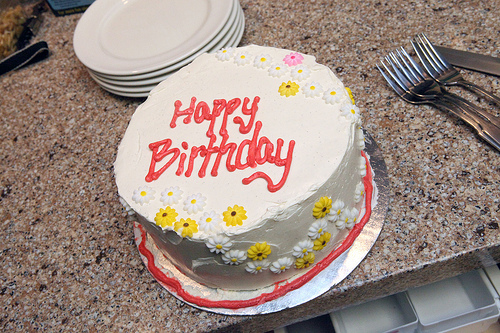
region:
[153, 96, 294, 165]
frosting that spells out Happy Birthday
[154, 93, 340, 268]
white frosted cake with flower decorations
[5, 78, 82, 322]
granite kitchen countertop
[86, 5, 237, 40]
stack of white plates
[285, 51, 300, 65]
pink flower on the cake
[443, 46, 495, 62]
knife on the countertop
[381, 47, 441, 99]
four forks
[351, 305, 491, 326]
white storage containers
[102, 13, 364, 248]
Birthday cake next to five plates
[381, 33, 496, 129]
knife and forks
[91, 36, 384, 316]
white birthday cake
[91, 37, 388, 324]
white birthday cake with red lettering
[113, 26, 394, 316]
white cake with daisy candy decorations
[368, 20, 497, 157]
four silver forks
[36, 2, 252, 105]
five white plates on a counter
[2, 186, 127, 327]
beige granite countertop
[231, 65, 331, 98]
yellow and white candy decorations atop a cake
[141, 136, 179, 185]
red icing B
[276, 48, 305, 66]
pink candy daisy decoration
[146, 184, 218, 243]
two yellow and two white daisy decorations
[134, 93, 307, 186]
letters in red frosting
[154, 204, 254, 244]
white and yellow frosting flowers on cake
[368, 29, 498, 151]
forks on countertop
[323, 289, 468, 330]
open drawer beneath counter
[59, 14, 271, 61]
plates stacked behind cake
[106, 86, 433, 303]
white uncut birthday cake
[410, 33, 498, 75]
knife laying behind forks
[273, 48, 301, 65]
pink flower on cake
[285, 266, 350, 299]
cake reflective tin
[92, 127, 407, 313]
red frosting around cake base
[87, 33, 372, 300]
The cake has words on it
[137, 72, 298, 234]
The cake has the words Happy Birthday on it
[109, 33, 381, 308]
The cake is decorated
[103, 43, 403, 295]
The cake has multiple colors on it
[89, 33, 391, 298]
The cake has tiny flowers on it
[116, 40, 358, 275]
The cake is decorated with different colored flowers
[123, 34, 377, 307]
The words Happy Birthday on the cake are red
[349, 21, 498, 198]
The forks are silver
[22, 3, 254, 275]
The picture has plates in it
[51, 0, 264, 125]
The picture has white plates in it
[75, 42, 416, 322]
a birthday cake on a granite counter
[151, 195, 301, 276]
white and yellow daisies on a birthday cake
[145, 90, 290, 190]
"happy birthday" written on a birthday cake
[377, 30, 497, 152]
several forks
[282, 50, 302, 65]
a pink daisy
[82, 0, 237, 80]
a stack of plates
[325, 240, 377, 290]
a cake tray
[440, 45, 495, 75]
a knife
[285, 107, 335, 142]
white frosting on a birthday cake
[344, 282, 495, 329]
white storage bins